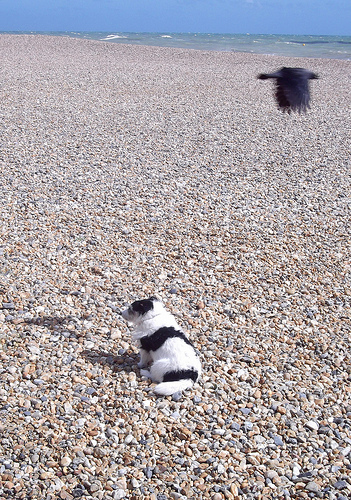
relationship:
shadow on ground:
[20, 312, 89, 340] [0, 34, 349, 498]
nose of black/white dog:
[119, 311, 123, 317] [120, 294, 202, 396]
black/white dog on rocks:
[120, 294, 202, 396] [62, 297, 310, 483]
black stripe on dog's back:
[143, 323, 187, 348] [141, 314, 205, 389]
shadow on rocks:
[20, 312, 89, 340] [0, 34, 350, 498]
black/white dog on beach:
[120, 294, 202, 396] [0, 30, 349, 498]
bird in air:
[252, 57, 322, 113] [210, 19, 335, 120]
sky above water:
[1, 0, 349, 33] [0, 31, 348, 55]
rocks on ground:
[58, 111, 92, 139] [10, 36, 225, 246]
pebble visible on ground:
[273, 437, 283, 444] [0, 34, 349, 498]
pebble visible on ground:
[153, 465, 162, 473] [0, 34, 349, 498]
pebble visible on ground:
[305, 481, 321, 491] [0, 34, 349, 498]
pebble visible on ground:
[305, 420, 319, 431] [0, 34, 349, 498]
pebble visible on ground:
[121, 432, 135, 444] [0, 34, 349, 498]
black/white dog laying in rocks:
[120, 294, 202, 396] [212, 405, 218, 412]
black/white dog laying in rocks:
[120, 294, 202, 396] [268, 432, 282, 445]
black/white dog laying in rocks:
[120, 294, 202, 396] [240, 350, 252, 363]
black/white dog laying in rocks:
[120, 294, 202, 396] [23, 362, 31, 377]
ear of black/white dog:
[136, 297, 154, 312] [120, 294, 202, 396]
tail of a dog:
[146, 366, 200, 399] [111, 244, 221, 404]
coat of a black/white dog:
[141, 316, 197, 381] [120, 294, 202, 396]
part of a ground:
[252, 398, 291, 442] [297, 236, 298, 237]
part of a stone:
[304, 421, 312, 428] [307, 418, 319, 430]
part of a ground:
[210, 411, 312, 474] [0, 122, 334, 434]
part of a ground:
[289, 414, 333, 471] [19, 102, 256, 229]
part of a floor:
[253, 371, 321, 436] [61, 434, 299, 477]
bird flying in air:
[257, 64, 323, 117] [274, 5, 304, 35]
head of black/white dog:
[118, 295, 163, 322] [120, 294, 202, 396]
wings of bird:
[278, 68, 311, 113] [242, 58, 316, 117]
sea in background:
[57, 11, 326, 92] [171, 7, 338, 56]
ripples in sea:
[99, 27, 175, 45] [1, 26, 349, 61]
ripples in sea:
[271, 36, 349, 54] [1, 26, 349, 61]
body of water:
[82, 25, 337, 55] [77, 32, 341, 62]